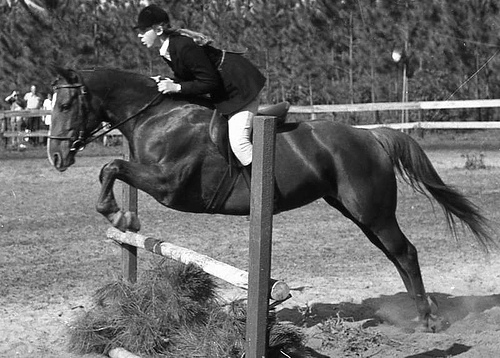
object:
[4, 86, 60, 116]
spectators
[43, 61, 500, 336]
horse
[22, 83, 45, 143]
man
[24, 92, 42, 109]
shirt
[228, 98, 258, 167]
pants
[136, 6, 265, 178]
rider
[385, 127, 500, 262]
tail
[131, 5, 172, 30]
cap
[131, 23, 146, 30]
brim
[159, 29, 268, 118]
jacket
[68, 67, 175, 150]
rein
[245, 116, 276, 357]
post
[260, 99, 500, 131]
fence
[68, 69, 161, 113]
mane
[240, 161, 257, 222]
boots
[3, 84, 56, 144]
people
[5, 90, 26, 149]
man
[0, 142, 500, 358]
field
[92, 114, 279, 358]
obstacle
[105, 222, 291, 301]
stick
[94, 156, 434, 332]
legs